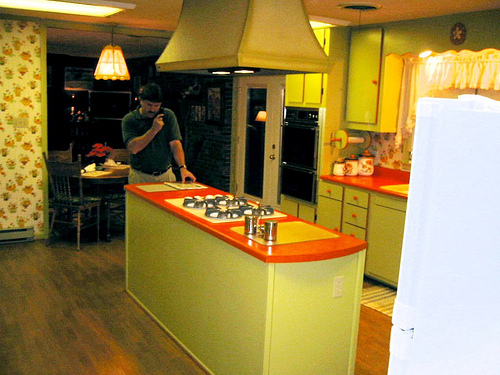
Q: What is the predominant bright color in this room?
A: Yellow.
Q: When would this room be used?
A: Mealtime.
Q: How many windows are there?
A: 1.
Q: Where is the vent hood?
A: Above the island.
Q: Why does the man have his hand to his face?
A: Talking on phone.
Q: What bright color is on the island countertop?
A: Orange.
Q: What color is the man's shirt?
A: Green.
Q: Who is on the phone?
A: Man.